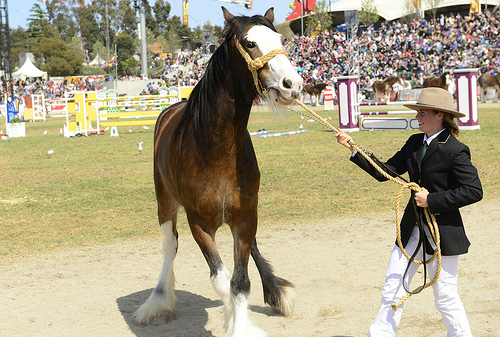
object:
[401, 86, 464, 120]
hat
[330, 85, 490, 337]
woman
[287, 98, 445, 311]
rope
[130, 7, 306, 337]
horse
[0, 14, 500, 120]
spectators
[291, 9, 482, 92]
stands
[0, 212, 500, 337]
sand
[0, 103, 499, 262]
grass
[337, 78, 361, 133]
fence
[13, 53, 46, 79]
tent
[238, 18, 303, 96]
white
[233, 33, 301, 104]
halter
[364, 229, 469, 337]
pants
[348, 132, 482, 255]
jacket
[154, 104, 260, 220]
brown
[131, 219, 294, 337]
legs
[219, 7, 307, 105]
face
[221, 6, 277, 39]
ears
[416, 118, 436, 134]
smiling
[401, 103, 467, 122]
section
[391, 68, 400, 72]
man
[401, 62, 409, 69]
elbow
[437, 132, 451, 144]
black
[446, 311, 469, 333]
trouser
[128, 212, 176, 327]
leg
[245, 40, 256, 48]
eye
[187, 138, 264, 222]
body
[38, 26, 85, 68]
tree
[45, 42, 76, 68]
leaves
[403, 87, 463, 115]
tan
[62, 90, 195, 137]
obstacles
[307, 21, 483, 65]
audience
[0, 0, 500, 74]
background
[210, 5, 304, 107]
head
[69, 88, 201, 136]
horse jump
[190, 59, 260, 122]
mane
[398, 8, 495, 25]
scaffold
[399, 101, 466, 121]
wide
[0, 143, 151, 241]
arena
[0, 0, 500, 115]
crowd